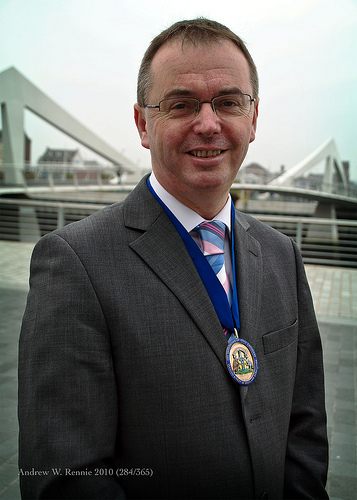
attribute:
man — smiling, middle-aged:
[17, 13, 343, 499]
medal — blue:
[144, 175, 263, 386]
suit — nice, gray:
[15, 170, 336, 495]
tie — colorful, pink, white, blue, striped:
[196, 221, 236, 313]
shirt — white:
[145, 172, 216, 242]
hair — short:
[151, 18, 245, 55]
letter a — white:
[17, 469, 25, 479]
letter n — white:
[22, 471, 29, 479]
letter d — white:
[30, 466, 37, 479]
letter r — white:
[34, 469, 40, 478]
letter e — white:
[37, 469, 42, 477]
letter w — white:
[50, 467, 65, 479]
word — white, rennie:
[63, 464, 94, 482]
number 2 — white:
[94, 464, 102, 480]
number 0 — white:
[98, 466, 106, 481]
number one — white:
[102, 467, 113, 480]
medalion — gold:
[217, 328, 264, 388]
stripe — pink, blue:
[201, 239, 224, 257]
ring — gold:
[232, 324, 242, 336]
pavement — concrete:
[301, 255, 356, 499]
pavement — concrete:
[0, 239, 30, 499]